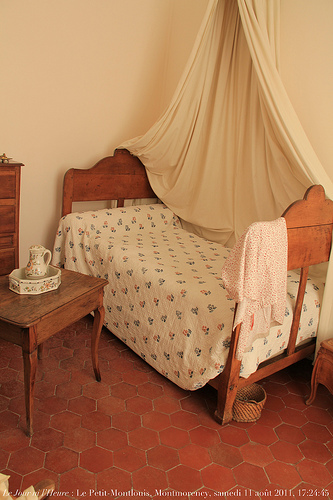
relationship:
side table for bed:
[303, 337, 332, 404] [50, 149, 330, 425]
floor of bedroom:
[1, 315, 331, 498] [0, 0, 332, 497]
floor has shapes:
[1, 315, 331, 498] [143, 448, 182, 469]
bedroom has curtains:
[0, 0, 332, 497] [120, 1, 332, 248]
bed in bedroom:
[50, 149, 330, 425] [0, 0, 332, 497]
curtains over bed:
[120, 1, 332, 248] [50, 149, 330, 425]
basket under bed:
[233, 383, 265, 421] [50, 149, 330, 425]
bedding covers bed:
[52, 206, 323, 392] [50, 149, 330, 425]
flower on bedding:
[183, 330, 192, 338] [52, 206, 323, 392]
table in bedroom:
[0, 270, 111, 436] [0, 0, 332, 497]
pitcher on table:
[25, 247, 53, 277] [0, 270, 111, 436]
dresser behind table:
[0, 163, 23, 291] [0, 270, 111, 436]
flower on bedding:
[144, 281, 154, 289] [52, 206, 323, 392]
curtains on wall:
[120, 1, 332, 248] [0, 1, 330, 274]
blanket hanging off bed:
[222, 220, 289, 359] [50, 149, 330, 425]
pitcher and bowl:
[25, 247, 53, 277] [6, 267, 60, 295]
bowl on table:
[6, 267, 60, 295] [0, 270, 111, 436]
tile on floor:
[166, 464, 204, 492] [1, 315, 331, 498]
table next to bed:
[0, 270, 111, 436] [50, 149, 330, 425]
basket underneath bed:
[233, 383, 265, 421] [50, 149, 330, 425]